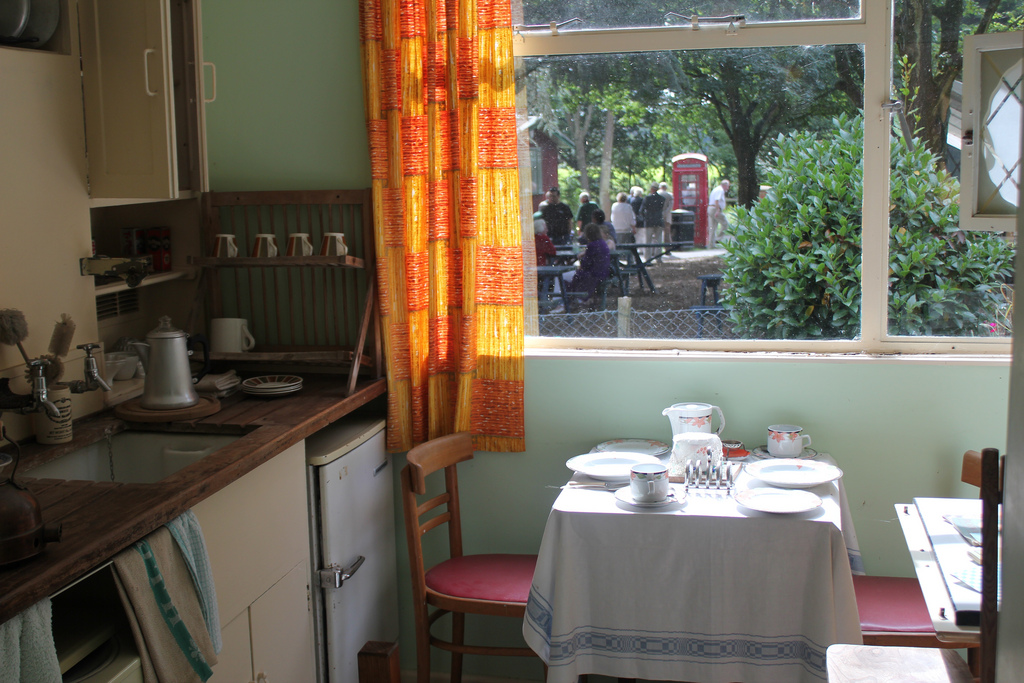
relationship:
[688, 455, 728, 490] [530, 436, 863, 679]
caddy on table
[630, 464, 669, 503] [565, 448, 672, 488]
cup side of plate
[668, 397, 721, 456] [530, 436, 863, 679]
pitcher on table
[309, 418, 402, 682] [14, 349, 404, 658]
fridge under counter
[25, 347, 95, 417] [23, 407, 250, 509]
faucets over sink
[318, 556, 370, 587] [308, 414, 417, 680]
handle on refrigerator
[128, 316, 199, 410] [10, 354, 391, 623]
cup on counter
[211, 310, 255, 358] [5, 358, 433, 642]
cup on counter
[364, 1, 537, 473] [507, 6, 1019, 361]
curtain in window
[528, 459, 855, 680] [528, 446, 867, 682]
table with table